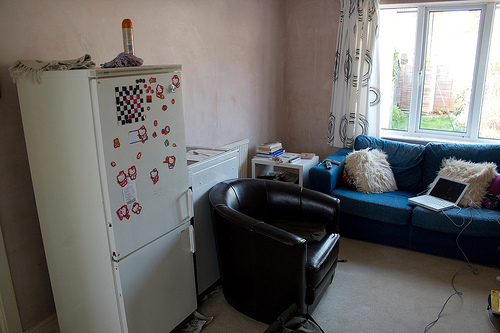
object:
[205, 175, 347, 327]
chair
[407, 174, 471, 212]
laptop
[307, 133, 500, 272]
couch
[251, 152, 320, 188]
table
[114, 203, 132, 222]
magnet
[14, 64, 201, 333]
refrigerator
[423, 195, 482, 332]
cord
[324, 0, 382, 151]
curtain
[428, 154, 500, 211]
pillow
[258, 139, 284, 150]
books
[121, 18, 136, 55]
aeresol can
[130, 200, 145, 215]
magnet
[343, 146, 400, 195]
pillow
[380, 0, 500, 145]
window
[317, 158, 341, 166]
remote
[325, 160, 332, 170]
remote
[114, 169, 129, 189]
magnet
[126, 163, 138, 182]
magnet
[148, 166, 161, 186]
magnet